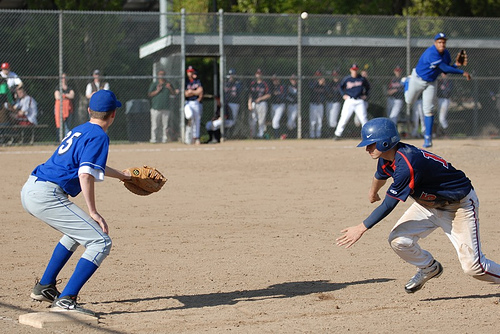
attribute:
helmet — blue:
[359, 117, 401, 150]